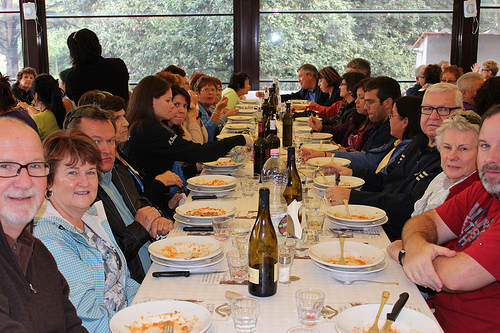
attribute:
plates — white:
[327, 305, 434, 332]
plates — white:
[327, 194, 389, 238]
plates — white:
[177, 165, 242, 292]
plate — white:
[146, 232, 224, 265]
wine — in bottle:
[247, 187, 281, 295]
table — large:
[227, 160, 327, 308]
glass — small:
[200, 277, 281, 327]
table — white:
[106, 91, 439, 331]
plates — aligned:
[331, 300, 431, 332]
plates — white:
[189, 88, 406, 331]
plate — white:
[306, 240, 388, 270]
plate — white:
[332, 296, 439, 330]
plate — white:
[111, 296, 219, 330]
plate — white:
[142, 234, 223, 264]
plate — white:
[326, 204, 386, 230]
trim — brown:
[237, 6, 263, 82]